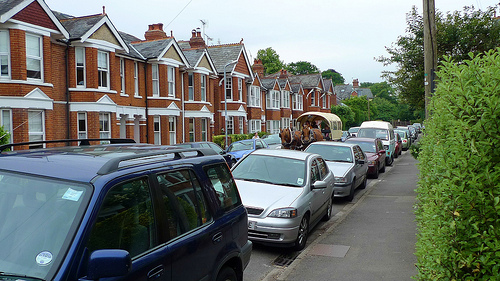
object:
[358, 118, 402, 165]
van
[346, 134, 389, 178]
car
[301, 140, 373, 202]
car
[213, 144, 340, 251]
car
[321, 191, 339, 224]
tire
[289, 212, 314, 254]
tire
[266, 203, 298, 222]
headlight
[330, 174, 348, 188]
headlight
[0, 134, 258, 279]
van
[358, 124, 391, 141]
windshield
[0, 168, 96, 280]
windshield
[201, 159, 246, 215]
window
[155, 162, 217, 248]
window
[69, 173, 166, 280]
window